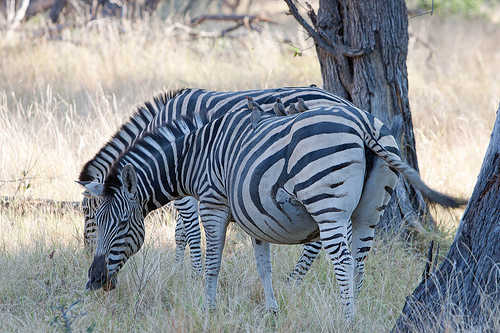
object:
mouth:
[84, 278, 105, 292]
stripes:
[275, 143, 361, 188]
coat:
[72, 103, 468, 331]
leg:
[307, 209, 362, 319]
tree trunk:
[385, 102, 499, 332]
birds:
[243, 95, 265, 114]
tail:
[358, 125, 470, 211]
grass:
[0, 0, 499, 332]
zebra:
[71, 102, 469, 330]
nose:
[85, 263, 103, 283]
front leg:
[198, 202, 231, 305]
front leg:
[171, 197, 202, 277]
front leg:
[171, 212, 186, 269]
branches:
[281, 0, 321, 40]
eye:
[114, 216, 129, 232]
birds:
[293, 96, 308, 113]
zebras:
[71, 80, 357, 286]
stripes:
[298, 190, 348, 206]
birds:
[246, 105, 262, 132]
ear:
[118, 162, 140, 199]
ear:
[71, 177, 105, 201]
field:
[1, 0, 498, 332]